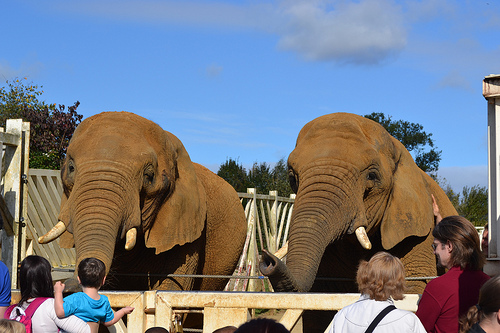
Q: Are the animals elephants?
A: Yes, all the animals are elephants.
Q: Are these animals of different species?
A: No, all the animals are elephants.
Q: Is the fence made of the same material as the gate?
A: Yes, both the fence and the gate are made of metal.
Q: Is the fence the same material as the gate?
A: Yes, both the fence and the gate are made of metal.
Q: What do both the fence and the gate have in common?
A: The material, both the fence and the gate are metallic.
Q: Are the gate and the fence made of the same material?
A: Yes, both the gate and the fence are made of metal.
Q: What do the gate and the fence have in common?
A: The material, both the gate and the fence are metallic.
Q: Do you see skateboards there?
A: No, there are no skateboards.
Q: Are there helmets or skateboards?
A: No, there are no skateboards or helmets.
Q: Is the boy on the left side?
A: Yes, the boy is on the left of the image.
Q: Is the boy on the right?
A: No, the boy is on the left of the image.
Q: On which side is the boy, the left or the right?
A: The boy is on the left of the image.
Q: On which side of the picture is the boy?
A: The boy is on the left of the image.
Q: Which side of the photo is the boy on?
A: The boy is on the left of the image.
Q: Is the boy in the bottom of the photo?
A: Yes, the boy is in the bottom of the image.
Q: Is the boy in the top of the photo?
A: No, the boy is in the bottom of the image.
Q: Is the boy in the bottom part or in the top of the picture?
A: The boy is in the bottom of the image.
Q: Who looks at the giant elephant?
A: The boy looks at the elephant.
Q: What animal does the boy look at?
A: The boy looks at the elephant.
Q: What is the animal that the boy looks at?
A: The animal is an elephant.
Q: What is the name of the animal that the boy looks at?
A: The animal is an elephant.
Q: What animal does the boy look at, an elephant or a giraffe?
A: The boy looks at an elephant.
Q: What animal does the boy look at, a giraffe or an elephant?
A: The boy looks at an elephant.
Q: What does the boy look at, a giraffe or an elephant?
A: The boy looks at an elephant.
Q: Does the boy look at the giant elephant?
A: Yes, the boy looks at the elephant.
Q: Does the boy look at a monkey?
A: No, the boy looks at the elephant.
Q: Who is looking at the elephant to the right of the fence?
A: The boy is looking at the elephant.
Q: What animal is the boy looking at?
A: The boy is looking at the elephant.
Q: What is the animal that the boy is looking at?
A: The animal is an elephant.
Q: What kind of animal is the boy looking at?
A: The boy is looking at the elephant.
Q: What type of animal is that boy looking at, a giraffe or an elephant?
A: The boy is looking at an elephant.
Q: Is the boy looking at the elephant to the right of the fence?
A: Yes, the boy is looking at the elephant.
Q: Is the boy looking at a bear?
A: No, the boy is looking at the elephant.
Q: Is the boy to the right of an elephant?
A: No, the boy is to the left of an elephant.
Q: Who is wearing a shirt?
A: The boy is wearing a shirt.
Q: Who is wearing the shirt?
A: The boy is wearing a shirt.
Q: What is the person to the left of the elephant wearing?
A: The boy is wearing a shirt.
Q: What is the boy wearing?
A: The boy is wearing a shirt.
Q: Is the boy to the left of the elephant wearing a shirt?
A: Yes, the boy is wearing a shirt.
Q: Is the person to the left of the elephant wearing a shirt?
A: Yes, the boy is wearing a shirt.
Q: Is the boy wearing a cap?
A: No, the boy is wearing a shirt.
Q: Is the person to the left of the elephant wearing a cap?
A: No, the boy is wearing a shirt.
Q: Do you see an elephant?
A: Yes, there is an elephant.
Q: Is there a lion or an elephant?
A: Yes, there is an elephant.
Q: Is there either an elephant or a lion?
A: Yes, there is an elephant.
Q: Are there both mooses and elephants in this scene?
A: No, there is an elephant but no mooses.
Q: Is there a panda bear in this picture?
A: No, there are no panda bears.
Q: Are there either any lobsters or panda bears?
A: No, there are no panda bears or lobsters.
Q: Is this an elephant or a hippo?
A: This is an elephant.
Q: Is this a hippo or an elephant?
A: This is an elephant.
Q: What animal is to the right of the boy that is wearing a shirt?
A: The animal is an elephant.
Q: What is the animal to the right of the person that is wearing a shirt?
A: The animal is an elephant.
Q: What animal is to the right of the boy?
A: The animal is an elephant.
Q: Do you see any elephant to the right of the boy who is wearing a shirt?
A: Yes, there is an elephant to the right of the boy.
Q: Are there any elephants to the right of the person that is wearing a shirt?
A: Yes, there is an elephant to the right of the boy.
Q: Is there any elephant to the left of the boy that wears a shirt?
A: No, the elephant is to the right of the boy.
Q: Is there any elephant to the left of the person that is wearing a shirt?
A: No, the elephant is to the right of the boy.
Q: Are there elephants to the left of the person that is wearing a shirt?
A: No, the elephant is to the right of the boy.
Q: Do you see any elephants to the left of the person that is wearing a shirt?
A: No, the elephant is to the right of the boy.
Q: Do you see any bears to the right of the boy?
A: No, there is an elephant to the right of the boy.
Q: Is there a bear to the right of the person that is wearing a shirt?
A: No, there is an elephant to the right of the boy.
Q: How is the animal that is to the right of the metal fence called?
A: The animal is an elephant.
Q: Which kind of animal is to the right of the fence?
A: The animal is an elephant.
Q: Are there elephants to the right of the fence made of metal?
A: Yes, there is an elephant to the right of the fence.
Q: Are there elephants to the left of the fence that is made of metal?
A: No, the elephant is to the right of the fence.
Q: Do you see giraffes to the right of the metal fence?
A: No, there is an elephant to the right of the fence.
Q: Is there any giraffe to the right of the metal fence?
A: No, there is an elephant to the right of the fence.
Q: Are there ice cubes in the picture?
A: No, there are no ice cubes.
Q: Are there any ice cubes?
A: No, there are no ice cubes.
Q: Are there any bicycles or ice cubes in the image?
A: No, there are no ice cubes or bicycles.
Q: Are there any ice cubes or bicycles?
A: No, there are no ice cubes or bicycles.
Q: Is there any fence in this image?
A: Yes, there is a fence.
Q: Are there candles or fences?
A: Yes, there is a fence.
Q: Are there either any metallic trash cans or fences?
A: Yes, there is a metal fence.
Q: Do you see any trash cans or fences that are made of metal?
A: Yes, the fence is made of metal.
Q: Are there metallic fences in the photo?
A: Yes, there is a metal fence.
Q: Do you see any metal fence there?
A: Yes, there is a metal fence.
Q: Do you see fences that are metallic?
A: Yes, there is a fence that is metallic.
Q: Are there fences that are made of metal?
A: Yes, there is a fence that is made of metal.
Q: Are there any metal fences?
A: Yes, there is a fence that is made of metal.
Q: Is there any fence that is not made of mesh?
A: Yes, there is a fence that is made of metal.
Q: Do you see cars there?
A: No, there are no cars.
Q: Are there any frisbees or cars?
A: No, there are no cars or frisbees.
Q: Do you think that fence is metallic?
A: Yes, the fence is metallic.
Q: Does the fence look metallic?
A: Yes, the fence is metallic.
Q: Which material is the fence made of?
A: The fence is made of metal.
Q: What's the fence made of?
A: The fence is made of metal.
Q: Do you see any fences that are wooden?
A: No, there is a fence but it is metallic.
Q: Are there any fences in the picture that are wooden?
A: No, there is a fence but it is metallic.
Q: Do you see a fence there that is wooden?
A: No, there is a fence but it is metallic.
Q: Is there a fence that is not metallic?
A: No, there is a fence but it is metallic.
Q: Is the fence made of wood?
A: No, the fence is made of metal.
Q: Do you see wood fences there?
A: No, there is a fence but it is made of metal.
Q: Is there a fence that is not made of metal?
A: No, there is a fence but it is made of metal.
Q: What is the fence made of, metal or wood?
A: The fence is made of metal.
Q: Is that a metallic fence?
A: Yes, that is a metallic fence.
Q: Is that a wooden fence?
A: No, that is a metallic fence.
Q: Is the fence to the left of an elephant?
A: Yes, the fence is to the left of an elephant.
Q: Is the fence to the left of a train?
A: No, the fence is to the left of an elephant.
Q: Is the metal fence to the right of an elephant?
A: No, the fence is to the left of an elephant.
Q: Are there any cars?
A: No, there are no cars.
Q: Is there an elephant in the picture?
A: Yes, there is an elephant.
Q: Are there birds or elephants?
A: Yes, there is an elephant.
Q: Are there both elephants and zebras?
A: No, there is an elephant but no zebras.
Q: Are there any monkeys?
A: No, there are no monkeys.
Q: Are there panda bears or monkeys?
A: No, there are no monkeys or panda bears.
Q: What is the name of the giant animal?
A: The animal is an elephant.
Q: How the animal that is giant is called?
A: The animal is an elephant.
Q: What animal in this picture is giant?
A: The animal is an elephant.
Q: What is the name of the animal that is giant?
A: The animal is an elephant.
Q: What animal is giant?
A: The animal is an elephant.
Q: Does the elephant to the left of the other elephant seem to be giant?
A: Yes, the elephant is giant.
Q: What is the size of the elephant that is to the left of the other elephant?
A: The elephant is giant.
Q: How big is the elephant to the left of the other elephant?
A: The elephant is giant.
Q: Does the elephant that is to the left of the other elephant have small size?
A: No, the elephant is giant.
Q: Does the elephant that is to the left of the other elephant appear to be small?
A: No, the elephant is giant.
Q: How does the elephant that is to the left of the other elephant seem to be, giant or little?
A: The elephant is giant.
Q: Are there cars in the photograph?
A: No, there are no cars.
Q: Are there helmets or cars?
A: No, there are no cars or helmets.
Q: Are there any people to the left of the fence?
A: No, the person is to the right of the fence.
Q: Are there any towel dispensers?
A: No, there are no towel dispensers.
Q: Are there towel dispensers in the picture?
A: No, there are no towel dispensers.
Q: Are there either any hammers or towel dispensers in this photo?
A: No, there are no towel dispensers or hammers.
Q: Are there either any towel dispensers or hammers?
A: No, there are no towel dispensers or hammers.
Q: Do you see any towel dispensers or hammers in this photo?
A: No, there are no towel dispensers or hammers.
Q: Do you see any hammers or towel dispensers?
A: No, there are no towel dispensers or hammers.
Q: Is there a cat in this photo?
A: No, there are no cats.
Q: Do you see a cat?
A: No, there are no cats.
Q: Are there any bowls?
A: No, there are no bowls.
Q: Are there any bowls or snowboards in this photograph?
A: No, there are no bowls or snowboards.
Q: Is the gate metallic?
A: Yes, the gate is metallic.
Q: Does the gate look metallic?
A: Yes, the gate is metallic.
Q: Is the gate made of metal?
A: Yes, the gate is made of metal.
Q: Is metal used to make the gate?
A: Yes, the gate is made of metal.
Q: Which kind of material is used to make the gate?
A: The gate is made of metal.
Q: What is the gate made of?
A: The gate is made of metal.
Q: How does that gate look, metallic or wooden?
A: The gate is metallic.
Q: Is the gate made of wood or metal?
A: The gate is made of metal.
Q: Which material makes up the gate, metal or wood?
A: The gate is made of metal.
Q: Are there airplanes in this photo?
A: No, there are no airplanes.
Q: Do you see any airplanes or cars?
A: No, there are no airplanes or cars.